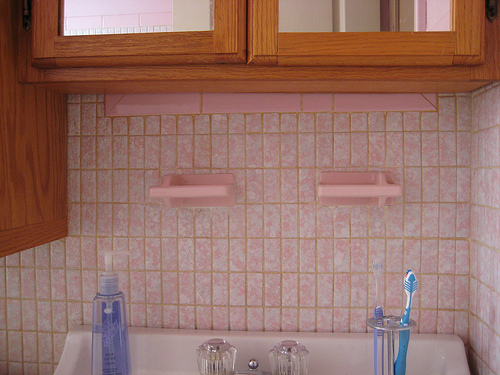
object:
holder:
[364, 315, 415, 374]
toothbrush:
[364, 252, 391, 374]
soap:
[143, 163, 239, 211]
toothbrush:
[394, 268, 427, 375]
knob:
[192, 338, 239, 375]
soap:
[88, 250, 137, 374]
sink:
[49, 322, 475, 374]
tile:
[199, 127, 257, 156]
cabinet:
[15, 0, 500, 123]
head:
[402, 269, 419, 293]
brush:
[391, 267, 421, 375]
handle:
[265, 336, 307, 375]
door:
[332, 0, 404, 49]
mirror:
[281, 0, 448, 31]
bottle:
[87, 246, 140, 374]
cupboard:
[11, 0, 499, 97]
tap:
[235, 344, 266, 374]